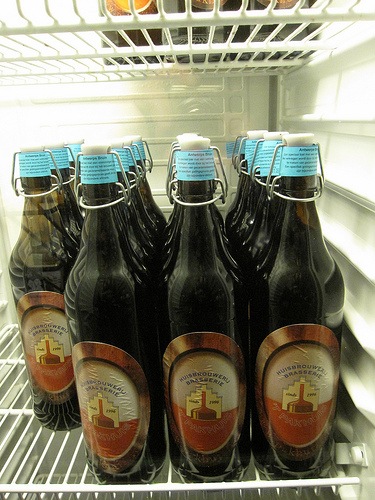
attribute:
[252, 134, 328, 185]
lable — blue